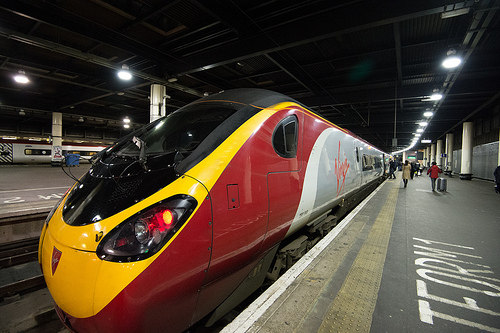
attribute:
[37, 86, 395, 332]
train — yellow red silver, red yellow white gre, red yellow, grey, red white yellow gra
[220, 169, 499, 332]
platform — grey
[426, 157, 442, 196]
person — walking away, waiting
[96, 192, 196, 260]
headlight — bright red, orange, round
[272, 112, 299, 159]
side window — black, long, odd-shaped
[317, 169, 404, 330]
line — yellow, faded, painted, long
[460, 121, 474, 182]
pillar — white, large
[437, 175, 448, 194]
luggage bag — grey, silver, small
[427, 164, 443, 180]
jacket — red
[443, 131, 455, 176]
pillar — white, large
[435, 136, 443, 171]
pillar — white, large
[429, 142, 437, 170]
pillar — white, large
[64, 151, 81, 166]
container — blue, light blue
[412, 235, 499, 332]
writing — white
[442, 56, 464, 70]
ceiling light — white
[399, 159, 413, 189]
person — walking away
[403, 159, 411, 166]
hair — dark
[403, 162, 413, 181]
coat — tan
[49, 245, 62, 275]
logo — red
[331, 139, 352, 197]
writing — red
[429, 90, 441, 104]
light — bright white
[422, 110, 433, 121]
light — bright white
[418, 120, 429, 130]
light — bright white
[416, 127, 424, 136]
light — bright white